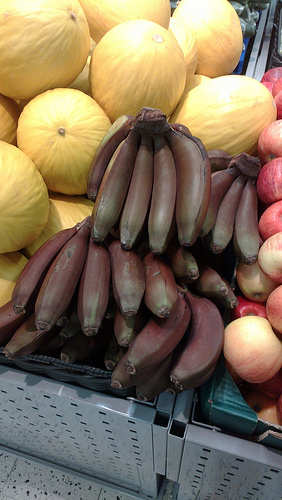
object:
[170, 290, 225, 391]
bananas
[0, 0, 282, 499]
fruit stand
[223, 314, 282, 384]
apples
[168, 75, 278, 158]
melons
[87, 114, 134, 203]
fruit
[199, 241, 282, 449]
box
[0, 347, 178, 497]
basket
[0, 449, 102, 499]
tile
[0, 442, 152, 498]
floor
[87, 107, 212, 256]
bunch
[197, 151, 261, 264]
bunch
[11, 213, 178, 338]
bunch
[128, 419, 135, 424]
holes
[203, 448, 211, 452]
hole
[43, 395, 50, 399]
hole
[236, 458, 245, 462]
hole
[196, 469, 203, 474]
hole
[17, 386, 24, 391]
hole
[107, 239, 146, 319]
banana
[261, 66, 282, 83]
apple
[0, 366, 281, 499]
side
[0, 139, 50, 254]
squash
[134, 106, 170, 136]
stem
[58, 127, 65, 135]
stem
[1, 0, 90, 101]
squash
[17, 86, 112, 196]
melon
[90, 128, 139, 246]
banana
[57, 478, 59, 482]
black spots